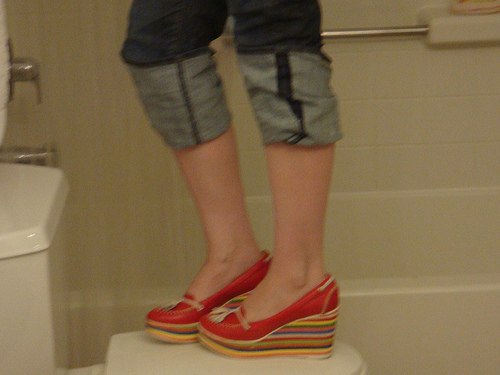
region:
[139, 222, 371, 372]
the shoes are colorful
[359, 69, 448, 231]
the wall is tiled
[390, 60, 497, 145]
the wall is tiled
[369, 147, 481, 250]
the wall is tiled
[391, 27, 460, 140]
the wall is tiled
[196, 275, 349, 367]
A woman's red shoe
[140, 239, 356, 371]
A woman's red shoes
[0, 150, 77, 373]
The top of a toilet tank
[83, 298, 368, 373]
The top of a toilet seat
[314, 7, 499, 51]
A metal handicap bathroom bar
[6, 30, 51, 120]
A bathtub water handle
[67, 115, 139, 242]
Brown Bathtub wall tile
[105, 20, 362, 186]
Blue jeans rolled up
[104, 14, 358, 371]
A woman standing on a toilet seat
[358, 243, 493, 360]
The edge of a bathtub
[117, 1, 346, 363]
a woman is standing on a toilet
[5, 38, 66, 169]
faucet handles for the tub and shower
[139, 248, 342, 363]
colorful red wedged shoes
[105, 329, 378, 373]
a white toilet lid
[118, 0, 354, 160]
blue jeans with rolled up legs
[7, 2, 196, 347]
a transparent shower curtain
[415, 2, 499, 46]
a shower soap dish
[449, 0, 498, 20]
soap resting in a soap dish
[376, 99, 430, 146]
eggshell white ceramic shower tile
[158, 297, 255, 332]
tan cording on top of shoes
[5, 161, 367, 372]
white toilet in bathroom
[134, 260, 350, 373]
multi-colored platform shoes on woman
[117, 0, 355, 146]
blue jeans rolled up to calf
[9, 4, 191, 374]
clear shower curtain in bathroom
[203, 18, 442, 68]
silver railing in the bathroom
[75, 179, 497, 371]
white bathtub in the bathroom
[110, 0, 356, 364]
woman standing on the toilet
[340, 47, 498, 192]
white tiles on the wall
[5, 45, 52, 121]
silver knob to turn water on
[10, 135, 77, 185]
silver faucet where water comes out of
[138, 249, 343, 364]
Pair of red heeled shoes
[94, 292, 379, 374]
Person standing on a lowered toilet seat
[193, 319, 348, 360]
Multi-color stripped shoe soles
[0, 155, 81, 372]
Shiny, white toilet cistern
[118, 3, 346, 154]
Folded blue pair of jeans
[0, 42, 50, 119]
Shiny silver colored handle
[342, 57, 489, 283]
Grey white colored tiled wall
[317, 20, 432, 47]
Silver colored metal railing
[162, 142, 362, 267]
Exposed pair of lower legs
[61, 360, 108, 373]
Connecting hose between the cistern and the seat